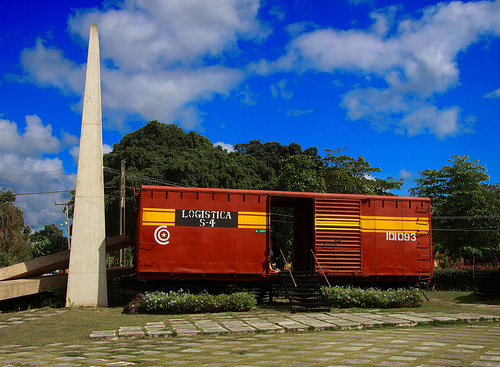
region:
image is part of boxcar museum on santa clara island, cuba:
[1, 0, 498, 365]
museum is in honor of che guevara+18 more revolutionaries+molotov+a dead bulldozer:
[0, 20, 450, 335]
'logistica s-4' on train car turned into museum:
[170, 205, 241, 230]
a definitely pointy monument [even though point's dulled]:
[61, 18, 113, 318]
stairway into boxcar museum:
[271, 238, 338, 320]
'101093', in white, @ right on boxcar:
[380, 225, 422, 244]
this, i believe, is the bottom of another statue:
[0, 226, 67, 311]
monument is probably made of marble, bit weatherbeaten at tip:
[56, 20, 116, 314]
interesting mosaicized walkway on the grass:
[0, 298, 499, 365]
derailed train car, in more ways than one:
[130, 175, 440, 313]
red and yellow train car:
[134, 176, 431, 277]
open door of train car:
[264, 200, 323, 271]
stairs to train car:
[281, 247, 332, 313]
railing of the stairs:
[278, 245, 332, 298]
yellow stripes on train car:
[135, 203, 430, 232]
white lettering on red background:
[385, 225, 416, 242]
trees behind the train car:
[100, 110, 486, 252]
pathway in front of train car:
[111, 298, 490, 347]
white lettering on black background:
[173, 207, 238, 230]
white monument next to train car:
[63, 22, 111, 307]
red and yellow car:
[139, 172, 411, 300]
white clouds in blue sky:
[0, 12, 57, 66]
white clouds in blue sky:
[15, 49, 66, 107]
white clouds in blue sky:
[8, 96, 63, 161]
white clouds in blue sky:
[122, 19, 187, 80]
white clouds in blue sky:
[119, 49, 177, 89]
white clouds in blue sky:
[165, 30, 210, 67]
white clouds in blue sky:
[202, 19, 249, 84]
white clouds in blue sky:
[265, 17, 349, 92]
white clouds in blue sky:
[365, 15, 430, 110]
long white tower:
[70, 19, 106, 306]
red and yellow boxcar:
[136, 175, 436, 287]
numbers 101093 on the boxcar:
[370, 223, 424, 255]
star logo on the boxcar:
[150, 220, 176, 262]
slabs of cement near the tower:
[2, 245, 67, 298]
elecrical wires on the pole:
[112, 145, 134, 232]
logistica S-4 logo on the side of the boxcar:
[175, 200, 238, 235]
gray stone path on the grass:
[141, 310, 346, 342]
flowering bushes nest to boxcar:
[125, 281, 260, 311]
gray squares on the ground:
[327, 333, 407, 365]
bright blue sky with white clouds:
[127, 20, 412, 147]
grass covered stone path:
[132, 317, 481, 357]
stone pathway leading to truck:
[158, 315, 463, 340]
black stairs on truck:
[281, 270, 345, 325]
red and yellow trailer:
[138, 187, 496, 260]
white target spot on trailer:
[148, 225, 178, 258]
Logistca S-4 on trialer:
[171, 205, 234, 233]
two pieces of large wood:
[21, 250, 56, 317]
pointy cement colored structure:
[63, 17, 111, 304]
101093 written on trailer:
[378, 221, 435, 253]